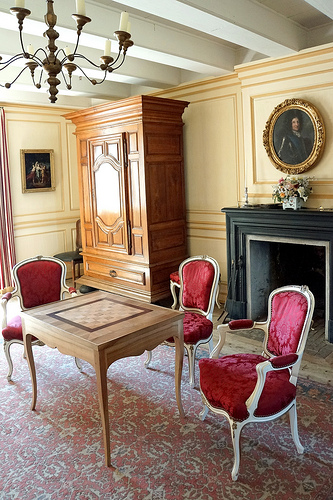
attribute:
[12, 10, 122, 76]
chandelier — brown brass, metal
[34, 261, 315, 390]
chairs — red, white, velvet, cushioned, queen anne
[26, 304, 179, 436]
checkers table — brown, in room, wooden, square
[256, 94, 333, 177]
picture — round, reproduction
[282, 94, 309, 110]
gold frame — decor appropriate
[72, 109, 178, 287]
wood cabinet — brown, tall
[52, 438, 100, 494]
carpet — red, white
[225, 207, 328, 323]
fireplace — black, old, simple, dark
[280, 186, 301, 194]
flowers — light colored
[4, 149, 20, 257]
curtain — red, white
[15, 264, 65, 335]
chair — in corner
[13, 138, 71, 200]
square frame — gold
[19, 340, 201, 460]
legs — curved